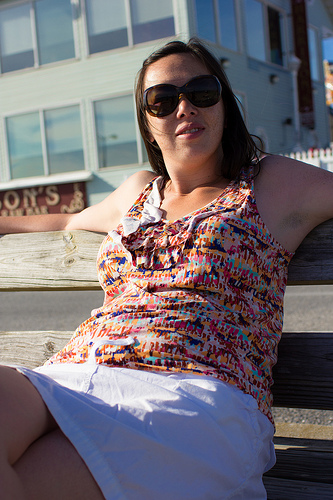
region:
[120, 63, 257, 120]
oversized brown sunglasses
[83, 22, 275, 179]
brunette girl wearing sunglasses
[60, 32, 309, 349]
brunette girl wearing a multi-colored tank top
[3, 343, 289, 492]
white denim mini-skirt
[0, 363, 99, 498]
female upper thighs in a white skirt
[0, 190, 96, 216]
partial wooden sign with cream letters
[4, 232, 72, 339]
wooden slats for a bench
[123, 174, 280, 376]
female torso in a multi-colored tank top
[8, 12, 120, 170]
windows in a white apartment building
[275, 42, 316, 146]
white lamppost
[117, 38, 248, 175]
large dark sunglasses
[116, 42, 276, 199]
woman with long brown hair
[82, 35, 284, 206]
woman with brown hair wearing sunglasses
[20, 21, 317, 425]
woman sitting outside on wooden bench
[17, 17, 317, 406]
woman wearing summer clothing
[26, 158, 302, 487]
sleeveless shirt and white skirt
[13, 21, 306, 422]
woman outside in hot weather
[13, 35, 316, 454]
woman relaxing outside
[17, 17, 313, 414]
woman outside on a sunny hot day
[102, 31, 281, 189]
woman with content relaxed expression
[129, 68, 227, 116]
the lady has sunglasses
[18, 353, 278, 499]
the lady has a white skirt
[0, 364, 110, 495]
the lady crosses her legs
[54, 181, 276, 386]
the ladys shirt is multi colored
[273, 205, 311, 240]
the lady needs to shave are armpit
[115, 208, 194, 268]
the shirt has a ruffle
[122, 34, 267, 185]
the lady has brown hair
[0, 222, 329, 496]
the lady is sitting on a bench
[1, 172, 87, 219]
the sign is red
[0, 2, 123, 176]
the building has windows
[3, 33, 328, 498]
woman relaxing in sun on a bench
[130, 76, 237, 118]
sunglasses on a woman's face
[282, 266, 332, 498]
shaded area on a bench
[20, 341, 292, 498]
skirt of a woman on bench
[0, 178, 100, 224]
store front sign on building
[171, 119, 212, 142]
mouth of a woman relaxing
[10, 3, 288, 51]
building windows in the background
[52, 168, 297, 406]
colorful tank top of a woman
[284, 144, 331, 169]
white picket fence in the background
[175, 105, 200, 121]
nose of a woman relaxing on bench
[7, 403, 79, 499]
woman's leg crossed on bench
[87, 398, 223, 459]
wrinkles in white skirt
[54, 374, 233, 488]
shadow on white skirt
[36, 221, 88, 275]
pattern in wood bench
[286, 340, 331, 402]
large black space in bench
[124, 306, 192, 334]
red and blue color on shirt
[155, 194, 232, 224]
tan on woman's skin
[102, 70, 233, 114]
sun glasses on woman's face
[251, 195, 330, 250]
woman's hairy arm pit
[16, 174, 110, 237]
large brown sign on building